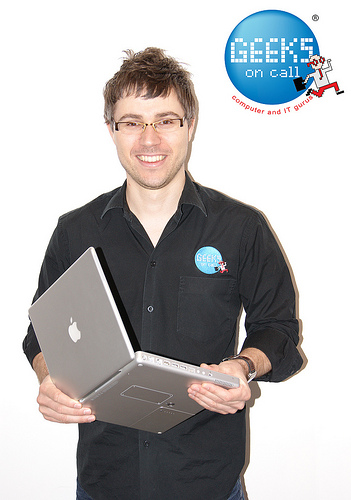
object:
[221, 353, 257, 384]
watch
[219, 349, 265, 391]
wrist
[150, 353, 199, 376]
ports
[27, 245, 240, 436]
computer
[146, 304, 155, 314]
black buttons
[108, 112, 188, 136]
glasses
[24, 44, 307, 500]
man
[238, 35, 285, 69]
letter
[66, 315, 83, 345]
logo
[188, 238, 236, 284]
sticker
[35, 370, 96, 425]
hands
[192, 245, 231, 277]
logo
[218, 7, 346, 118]
logo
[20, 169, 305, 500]
shirt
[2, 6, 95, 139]
wall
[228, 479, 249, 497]
pants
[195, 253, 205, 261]
letter